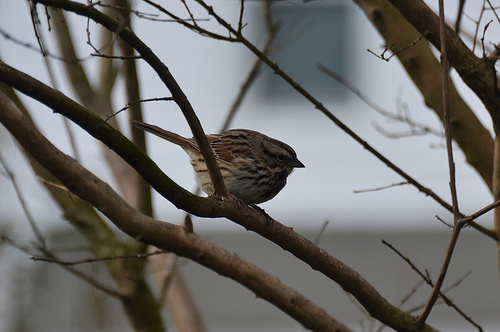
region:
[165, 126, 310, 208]
a puffy bird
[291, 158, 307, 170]
the beak of the bird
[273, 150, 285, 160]
the eye of the bird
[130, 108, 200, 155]
the tail of the bird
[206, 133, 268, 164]
the wing of the bird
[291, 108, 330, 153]
the grey sky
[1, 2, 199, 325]
the branches of the tree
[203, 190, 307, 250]
the part of branch the bird is sitting on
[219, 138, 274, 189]
the feathers of the bird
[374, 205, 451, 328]
branches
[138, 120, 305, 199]
A bird on the branch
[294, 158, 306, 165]
The beak of the bird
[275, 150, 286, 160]
The right eye of the bird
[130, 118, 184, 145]
The tail of the bird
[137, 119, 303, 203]
The bird is small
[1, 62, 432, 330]
Branches beneath the bird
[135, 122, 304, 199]
The bird has brown feathers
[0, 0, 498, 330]
A bird in a leafless tree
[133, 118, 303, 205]
The bird is sitting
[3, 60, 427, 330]
A branch below the bird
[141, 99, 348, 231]
Small brown bird on branch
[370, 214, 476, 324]
Small brown branch on tree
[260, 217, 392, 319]
Small brown branch on tree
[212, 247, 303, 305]
Small brown branch on tree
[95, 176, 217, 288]
Small brown branch on tree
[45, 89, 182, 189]
Small brown branch on tree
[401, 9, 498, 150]
Small brown branch on tree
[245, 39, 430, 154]
Small brown branch on tree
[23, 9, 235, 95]
Small brown branch on tree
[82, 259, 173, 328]
Small brown branch on tree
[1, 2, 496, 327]
Natural habitat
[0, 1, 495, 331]
Group of tree branches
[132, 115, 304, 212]
Small bird on a tree branch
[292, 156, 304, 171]
Beak of the bird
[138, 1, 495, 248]
Thin tree branch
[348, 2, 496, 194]
Set of thick tree branches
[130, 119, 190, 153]
Tail of the bird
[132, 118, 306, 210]
Small bird at rest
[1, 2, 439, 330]
Branch shaped like a pitch fork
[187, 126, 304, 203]
Body of the bird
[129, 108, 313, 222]
bird in a tree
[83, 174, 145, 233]
branch of a tree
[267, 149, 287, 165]
eye of the bird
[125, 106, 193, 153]
tail of the bird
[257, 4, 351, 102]
window on the building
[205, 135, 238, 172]
wings on the bird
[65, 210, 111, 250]
green on the tree branch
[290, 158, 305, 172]
beak on the bird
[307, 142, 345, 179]
white house in the back ground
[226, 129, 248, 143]
brown stripe on the bird